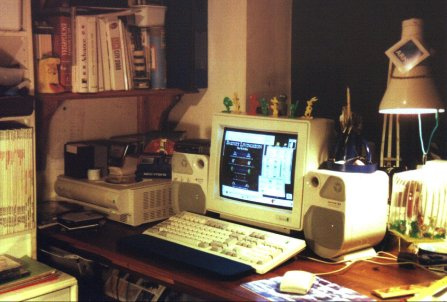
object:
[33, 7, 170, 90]
books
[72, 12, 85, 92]
book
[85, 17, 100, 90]
book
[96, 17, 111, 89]
book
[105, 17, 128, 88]
book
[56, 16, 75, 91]
book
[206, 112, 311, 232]
computer monitor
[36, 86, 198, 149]
shelf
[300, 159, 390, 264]
speaker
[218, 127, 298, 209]
screen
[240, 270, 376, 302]
mouse pad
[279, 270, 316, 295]
mouse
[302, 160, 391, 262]
cpu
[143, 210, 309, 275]
keyboard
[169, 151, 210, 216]
speaker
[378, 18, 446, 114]
lamp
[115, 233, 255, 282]
cushion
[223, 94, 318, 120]
figurine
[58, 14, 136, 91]
books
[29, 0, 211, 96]
shelf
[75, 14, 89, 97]
book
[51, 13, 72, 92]
book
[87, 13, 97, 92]
book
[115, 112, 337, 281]
computer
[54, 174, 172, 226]
fax machine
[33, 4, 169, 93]
white book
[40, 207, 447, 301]
desk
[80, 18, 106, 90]
book